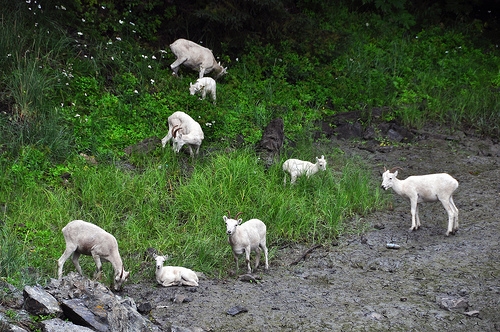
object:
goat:
[166, 39, 230, 80]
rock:
[21, 286, 60, 319]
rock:
[38, 316, 97, 332]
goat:
[221, 210, 269, 275]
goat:
[378, 166, 460, 236]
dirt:
[0, 130, 500, 332]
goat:
[55, 218, 130, 292]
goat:
[280, 154, 326, 186]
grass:
[0, 139, 396, 288]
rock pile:
[0, 271, 167, 332]